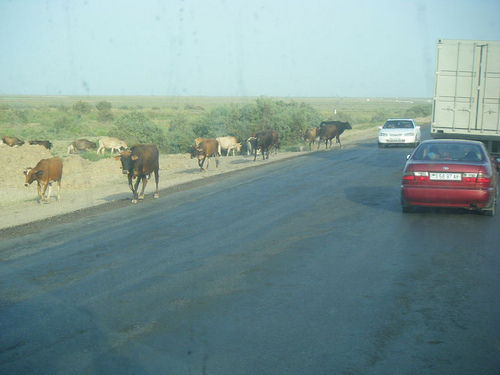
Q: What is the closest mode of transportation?
A: Car.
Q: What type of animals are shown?
A: Cows.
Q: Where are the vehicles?
A: On the road.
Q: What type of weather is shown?
A: Clear.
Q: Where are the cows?
A: Left side of the road.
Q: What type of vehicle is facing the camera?
A: A white car.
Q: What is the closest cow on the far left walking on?
A: Dirt.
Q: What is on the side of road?
A: Cows.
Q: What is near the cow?
A: Bushes.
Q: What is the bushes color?
A: Green.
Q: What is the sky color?
A: Blue.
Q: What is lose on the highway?
A: Several cows.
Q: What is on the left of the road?
A: A car.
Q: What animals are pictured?
A: Cows.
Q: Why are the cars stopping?
A: Cows on the road.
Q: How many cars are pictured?
A: 2.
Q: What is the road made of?
A: Asphalt.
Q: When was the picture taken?
A: Daytime.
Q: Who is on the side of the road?
A: The cows.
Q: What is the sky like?
A: Clear.